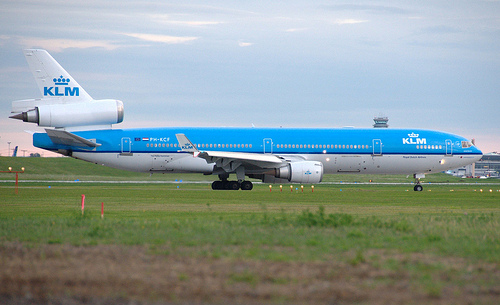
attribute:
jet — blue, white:
[7, 50, 485, 192]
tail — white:
[25, 49, 115, 130]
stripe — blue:
[42, 149, 485, 158]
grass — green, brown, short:
[1, 158, 498, 303]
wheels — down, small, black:
[211, 181, 258, 192]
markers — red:
[78, 191, 107, 219]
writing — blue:
[42, 86, 79, 95]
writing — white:
[401, 137, 428, 145]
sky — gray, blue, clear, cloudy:
[1, 2, 499, 156]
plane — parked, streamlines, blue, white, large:
[9, 47, 486, 191]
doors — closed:
[118, 135, 456, 158]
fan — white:
[277, 164, 293, 180]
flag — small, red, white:
[141, 136, 151, 143]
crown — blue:
[52, 74, 72, 86]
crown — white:
[407, 131, 422, 138]